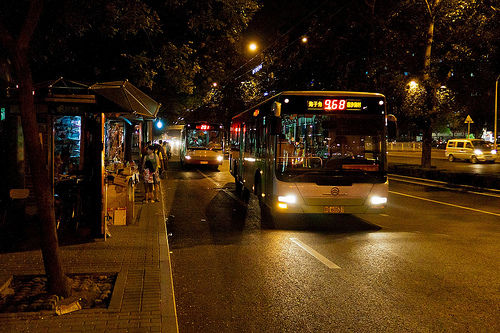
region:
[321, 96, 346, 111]
the bus number is 968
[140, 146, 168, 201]
the woman is standing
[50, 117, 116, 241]
the booth is green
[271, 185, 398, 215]
the bus's headlights are on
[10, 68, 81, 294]
the tree is brown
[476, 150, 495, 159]
the car's headlights are on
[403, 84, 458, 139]
the tree's leaves are green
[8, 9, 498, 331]
it is night time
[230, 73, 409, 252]
the bus is driving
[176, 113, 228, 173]
the bus is driving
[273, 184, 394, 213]
Two headlights are turned on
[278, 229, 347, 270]
A white line on the street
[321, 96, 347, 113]
Number 968 on the bus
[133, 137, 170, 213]
People standing on the sidewalk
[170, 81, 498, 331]
Two buses on the street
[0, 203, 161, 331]
Bricks on the sidewalk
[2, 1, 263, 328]
A tree on the sidewalk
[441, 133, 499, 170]
A van with its headlights on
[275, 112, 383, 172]
Reflections on the window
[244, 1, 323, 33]
The sky is dark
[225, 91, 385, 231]
a bus on a road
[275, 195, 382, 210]
lights on a bus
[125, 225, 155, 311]
a blocked side walk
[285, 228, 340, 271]
a white line on the road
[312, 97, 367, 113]
a number on the bus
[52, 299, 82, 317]
a paper on the ground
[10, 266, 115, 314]
a tree trunk in a square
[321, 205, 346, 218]
a tag on the bus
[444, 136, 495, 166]
a van on a road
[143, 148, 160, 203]
people on the sidewalk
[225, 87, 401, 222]
a green and white city bus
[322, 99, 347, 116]
number 968 on city bus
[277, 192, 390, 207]
two bright lights on bus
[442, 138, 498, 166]
a van with lights on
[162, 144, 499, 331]
a lit street area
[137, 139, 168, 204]
people standing on side walk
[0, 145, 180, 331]
a brick side walk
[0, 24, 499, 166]
a beautiful lit area of trees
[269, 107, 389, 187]
windshield of city bus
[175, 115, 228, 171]
city bus with bright lights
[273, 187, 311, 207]
lights on the bus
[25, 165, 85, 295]
a tree trunk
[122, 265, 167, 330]
the sidewalk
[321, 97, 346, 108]
numbers on the bus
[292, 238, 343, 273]
white line on the street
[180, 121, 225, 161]
a bus on the road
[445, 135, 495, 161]
a van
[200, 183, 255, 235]
a shadow on the ground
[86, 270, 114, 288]
rocks on the ground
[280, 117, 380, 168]
the windshield on the bus